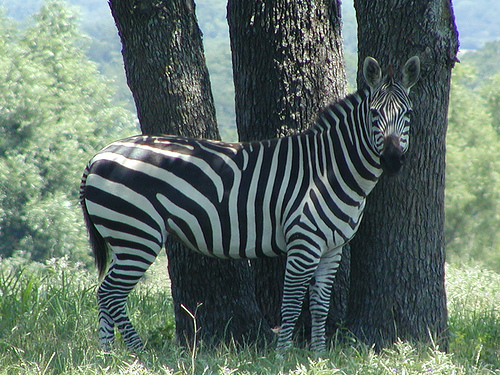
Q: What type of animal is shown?
A: A zebra.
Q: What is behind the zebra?
A: Tree trunks.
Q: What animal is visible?
A: Zebra.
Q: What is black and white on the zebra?
A: Stripes.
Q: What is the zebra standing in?
A: Grass.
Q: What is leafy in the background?
A: Trees.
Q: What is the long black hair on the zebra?
A: Tail.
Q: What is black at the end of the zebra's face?
A: Nose.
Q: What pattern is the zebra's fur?
A: Striped.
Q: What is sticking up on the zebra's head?
A: Ears.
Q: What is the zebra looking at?
A: Camera.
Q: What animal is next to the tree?
A: A zebra.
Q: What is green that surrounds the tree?
A: Grass.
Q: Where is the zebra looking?
A: Towards the camera.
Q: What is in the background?
A: Trees.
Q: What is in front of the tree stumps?
A: A zebra.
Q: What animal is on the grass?
A: A zebra.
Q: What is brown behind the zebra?
A: A tree stump.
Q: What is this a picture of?
A: Zebra.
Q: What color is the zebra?
A: Black and White.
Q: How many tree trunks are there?
A: Three.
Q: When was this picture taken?
A: Daytime.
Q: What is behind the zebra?
A: Trees.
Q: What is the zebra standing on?
A: Grass.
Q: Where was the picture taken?
A: Near a group of trees.